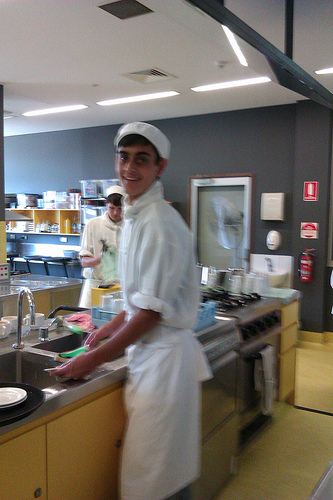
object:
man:
[50, 118, 214, 498]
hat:
[113, 117, 172, 159]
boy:
[46, 118, 206, 499]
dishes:
[42, 361, 74, 374]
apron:
[115, 328, 205, 499]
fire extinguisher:
[296, 245, 316, 285]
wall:
[293, 100, 328, 410]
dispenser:
[265, 228, 283, 250]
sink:
[248, 266, 284, 281]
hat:
[104, 182, 124, 200]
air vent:
[123, 65, 172, 80]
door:
[235, 324, 280, 440]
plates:
[0, 383, 27, 408]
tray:
[0, 381, 45, 427]